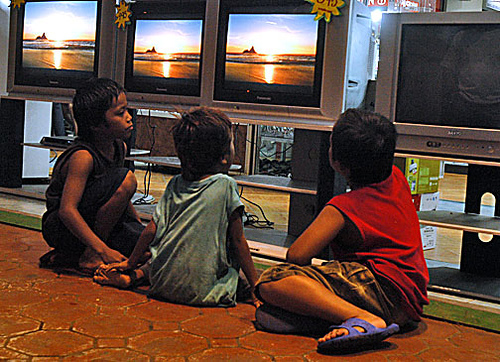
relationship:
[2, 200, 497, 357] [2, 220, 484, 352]
stone on ground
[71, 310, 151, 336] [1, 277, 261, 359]
red stone on ground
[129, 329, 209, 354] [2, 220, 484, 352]
brick on ground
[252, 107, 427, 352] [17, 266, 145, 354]
boy sitting on floor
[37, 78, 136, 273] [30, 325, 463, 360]
boy on floor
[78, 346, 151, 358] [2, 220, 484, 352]
brick on ground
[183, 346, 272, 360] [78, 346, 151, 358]
brick on brick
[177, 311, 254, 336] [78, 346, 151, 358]
brick on brick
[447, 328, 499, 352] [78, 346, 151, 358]
brick on brick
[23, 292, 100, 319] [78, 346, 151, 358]
brick on brick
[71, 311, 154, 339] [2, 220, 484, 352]
brick on ground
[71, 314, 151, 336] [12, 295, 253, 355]
brick on ground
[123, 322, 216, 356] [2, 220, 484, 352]
brick on ground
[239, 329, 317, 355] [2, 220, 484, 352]
brick on ground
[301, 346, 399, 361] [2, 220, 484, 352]
brick on ground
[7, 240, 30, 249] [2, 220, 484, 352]
brick on ground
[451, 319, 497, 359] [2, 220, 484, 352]
stone on ground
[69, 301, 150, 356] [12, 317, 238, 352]
red stone on ground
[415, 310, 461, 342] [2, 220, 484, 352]
stone on ground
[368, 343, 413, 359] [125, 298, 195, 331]
stone on ground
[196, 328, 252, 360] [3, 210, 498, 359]
red stone on ground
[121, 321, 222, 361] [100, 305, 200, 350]
stone on ground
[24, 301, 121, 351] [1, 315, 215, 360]
stone on ground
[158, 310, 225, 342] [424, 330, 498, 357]
brick on ground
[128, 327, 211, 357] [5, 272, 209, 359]
red brick on ground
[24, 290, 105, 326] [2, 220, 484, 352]
brick on ground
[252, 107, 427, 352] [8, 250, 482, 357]
boy on floor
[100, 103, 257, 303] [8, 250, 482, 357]
boy on floor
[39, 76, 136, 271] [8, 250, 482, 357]
boy on floor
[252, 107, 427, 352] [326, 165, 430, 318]
boy wears red shirt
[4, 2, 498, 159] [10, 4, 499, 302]
televisions on shelves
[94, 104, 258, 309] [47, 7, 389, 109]
boy look televisions.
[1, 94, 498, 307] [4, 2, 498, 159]
shelves under televisions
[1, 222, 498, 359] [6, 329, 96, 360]
floor made of tiles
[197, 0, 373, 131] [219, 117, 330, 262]
televisions on shelf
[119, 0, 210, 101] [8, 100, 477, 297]
tv on shelf